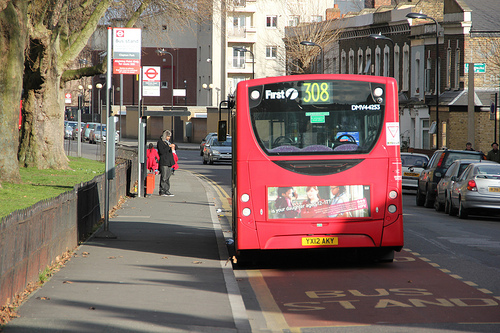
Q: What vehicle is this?
A: Bus.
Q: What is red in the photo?
A: The bus.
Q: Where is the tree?
A: By the bus.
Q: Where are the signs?
A: On the left of the bus.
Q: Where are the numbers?
A: On the bus.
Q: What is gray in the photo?
A: The sidewalk.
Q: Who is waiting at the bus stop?
A: Passengers.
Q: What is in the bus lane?
A: A bus.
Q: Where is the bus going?
A: To the bus stop.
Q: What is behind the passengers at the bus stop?
A: Trees.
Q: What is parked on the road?
A: Cars.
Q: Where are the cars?
A: By the buildings.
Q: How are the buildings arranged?
A: In a row.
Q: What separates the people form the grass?
A: A brick wall.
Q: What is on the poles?
A: Signs.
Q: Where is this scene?
A: A city.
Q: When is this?
A: During the day.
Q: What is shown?
A: A bus.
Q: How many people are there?
A: Four.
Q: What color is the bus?
A: Red.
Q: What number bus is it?
A: 308.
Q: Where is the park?
A: On the left.